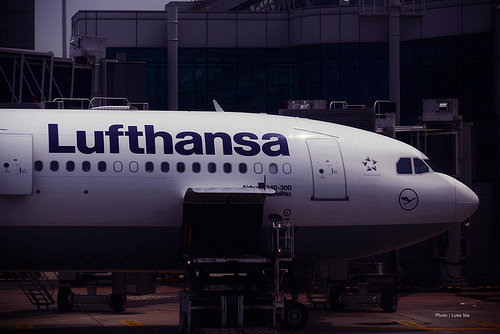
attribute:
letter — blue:
[40, 118, 76, 155]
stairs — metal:
[8, 266, 56, 313]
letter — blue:
[261, 131, 291, 156]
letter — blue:
[198, 132, 243, 158]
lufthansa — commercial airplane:
[41, 117, 294, 167]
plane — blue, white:
[4, 67, 484, 321]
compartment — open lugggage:
[174, 175, 284, 280]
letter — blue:
[59, 100, 360, 190]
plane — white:
[7, 99, 482, 244]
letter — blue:
[123, 121, 145, 160]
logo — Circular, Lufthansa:
[52, 104, 324, 179]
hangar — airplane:
[0, 1, 429, 113]